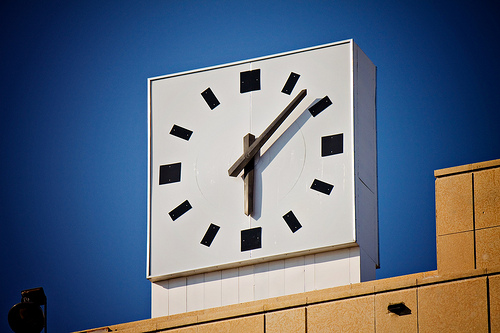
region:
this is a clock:
[100, 30, 430, 293]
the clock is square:
[113, 3, 401, 285]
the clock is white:
[89, 5, 426, 277]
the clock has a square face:
[111, 20, 420, 288]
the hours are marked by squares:
[228, 218, 270, 253]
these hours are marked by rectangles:
[275, 194, 322, 250]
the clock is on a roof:
[110, 11, 417, 331]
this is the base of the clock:
[122, 227, 395, 312]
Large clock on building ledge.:
[127, 34, 496, 332]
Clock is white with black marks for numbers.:
[135, 35, 378, 320]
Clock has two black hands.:
[228, 88, 309, 216]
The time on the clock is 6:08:
[143, 36, 381, 320]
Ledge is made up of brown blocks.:
[70, 155, 497, 332]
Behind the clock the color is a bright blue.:
[6, 4, 498, 331]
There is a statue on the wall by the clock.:
[4, 286, 49, 331]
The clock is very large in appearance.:
[145, 36, 387, 320]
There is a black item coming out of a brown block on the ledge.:
[385, 300, 412, 319]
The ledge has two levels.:
[68, 158, 498, 332]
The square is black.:
[230, 63, 268, 97]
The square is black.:
[152, 154, 192, 196]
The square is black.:
[228, 219, 273, 254]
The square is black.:
[311, 127, 346, 165]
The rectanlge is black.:
[196, 83, 226, 115]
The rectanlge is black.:
[163, 119, 199, 144]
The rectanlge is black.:
[159, 193, 199, 229]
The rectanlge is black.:
[192, 213, 224, 250]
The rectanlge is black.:
[281, 204, 311, 243]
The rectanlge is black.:
[306, 171, 336, 201]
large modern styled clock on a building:
[127, 39, 364, 310]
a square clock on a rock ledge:
[146, 33, 353, 274]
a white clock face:
[145, 43, 375, 303]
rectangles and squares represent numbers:
[159, 70, 341, 250]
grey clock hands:
[231, 81, 306, 219]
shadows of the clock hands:
[246, 92, 325, 216]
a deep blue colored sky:
[0, 3, 499, 325]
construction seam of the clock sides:
[350, 164, 377, 198]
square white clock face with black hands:
[141, 36, 381, 266]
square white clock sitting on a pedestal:
[143, 36, 388, 320]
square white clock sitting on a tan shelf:
[140, 30, 382, 330]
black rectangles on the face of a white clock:
[157, 66, 349, 253]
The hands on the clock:
[217, 75, 330, 222]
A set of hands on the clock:
[213, 85, 322, 217]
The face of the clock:
[157, 70, 350, 258]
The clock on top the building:
[116, 40, 403, 280]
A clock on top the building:
[121, 37, 400, 301]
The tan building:
[98, 161, 498, 330]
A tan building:
[105, 158, 494, 328]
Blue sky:
[21, 2, 144, 270]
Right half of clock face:
[247, 62, 359, 250]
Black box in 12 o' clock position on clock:
[234, 59, 265, 101]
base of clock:
[149, 259, 363, 302]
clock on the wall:
[114, 62, 412, 289]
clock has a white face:
[121, 57, 373, 259]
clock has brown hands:
[219, 85, 290, 212]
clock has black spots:
[143, 57, 368, 256]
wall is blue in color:
[391, 17, 468, 257]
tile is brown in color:
[447, 168, 491, 320]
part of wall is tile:
[441, 175, 493, 308]